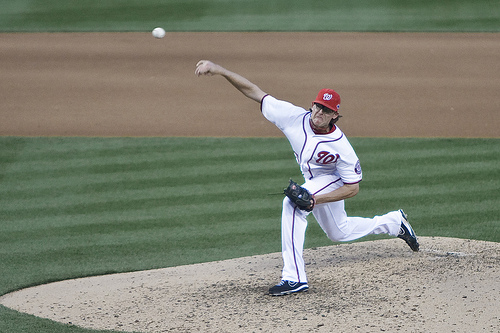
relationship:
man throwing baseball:
[193, 54, 422, 297] [148, 22, 168, 42]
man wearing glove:
[193, 54, 422, 297] [282, 177, 316, 216]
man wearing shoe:
[193, 54, 422, 297] [391, 207, 426, 249]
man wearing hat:
[193, 54, 422, 297] [312, 87, 345, 113]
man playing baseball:
[193, 54, 422, 297] [148, 22, 168, 42]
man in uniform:
[193, 54, 422, 297] [264, 122, 391, 278]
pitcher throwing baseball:
[193, 54, 422, 297] [148, 22, 168, 42]